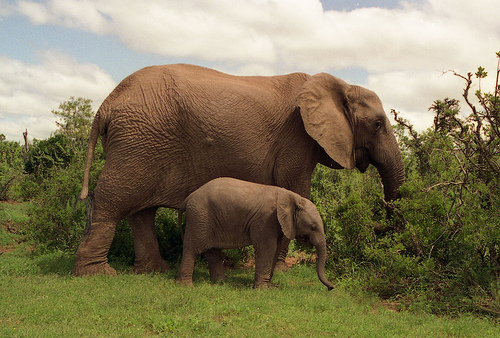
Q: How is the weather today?
A: It is cloudy.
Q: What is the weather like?
A: It is cloudy.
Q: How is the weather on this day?
A: It is cloudy.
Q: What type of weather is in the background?
A: It is cloudy.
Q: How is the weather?
A: It is cloudy.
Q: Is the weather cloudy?
A: Yes, it is cloudy.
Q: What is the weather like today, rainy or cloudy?
A: It is cloudy.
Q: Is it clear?
A: No, it is cloudy.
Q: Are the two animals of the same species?
A: Yes, all the animals are elephants.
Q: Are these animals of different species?
A: No, all the animals are elephants.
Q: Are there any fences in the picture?
A: No, there are no fences.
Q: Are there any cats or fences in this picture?
A: No, there are no fences or cats.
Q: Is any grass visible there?
A: Yes, there is grass.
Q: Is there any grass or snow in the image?
A: Yes, there is grass.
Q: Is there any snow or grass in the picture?
A: Yes, there is grass.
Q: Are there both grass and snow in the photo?
A: No, there is grass but no snow.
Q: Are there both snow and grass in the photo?
A: No, there is grass but no snow.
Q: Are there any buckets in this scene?
A: No, there are no buckets.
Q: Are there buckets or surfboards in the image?
A: No, there are no buckets or surfboards.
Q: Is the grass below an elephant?
A: Yes, the grass is below an elephant.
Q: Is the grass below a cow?
A: No, the grass is below an elephant.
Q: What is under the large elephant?
A: The grass is under the elephant.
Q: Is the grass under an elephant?
A: Yes, the grass is under an elephant.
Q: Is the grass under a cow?
A: No, the grass is under an elephant.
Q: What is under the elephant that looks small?
A: The grass is under the elephant.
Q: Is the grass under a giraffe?
A: No, the grass is under an elephant.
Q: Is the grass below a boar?
A: No, the grass is below the elephant.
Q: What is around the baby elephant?
A: The grass is around the elephant.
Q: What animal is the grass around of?
A: The grass is around the elephant.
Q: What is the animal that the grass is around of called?
A: The animal is an elephant.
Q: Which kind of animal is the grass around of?
A: The grass is around the elephant.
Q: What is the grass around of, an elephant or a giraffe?
A: The grass is around an elephant.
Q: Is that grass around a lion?
A: No, the grass is around the elephant.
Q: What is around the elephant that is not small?
A: The grass is around the elephant.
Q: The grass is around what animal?
A: The grass is around the elephant.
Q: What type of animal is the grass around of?
A: The grass is around the elephant.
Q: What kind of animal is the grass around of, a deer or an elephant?
A: The grass is around an elephant.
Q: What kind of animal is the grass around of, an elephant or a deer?
A: The grass is around an elephant.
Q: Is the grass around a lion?
A: No, the grass is around an elephant.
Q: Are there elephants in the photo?
A: Yes, there is an elephant.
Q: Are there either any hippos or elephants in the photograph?
A: Yes, there is an elephant.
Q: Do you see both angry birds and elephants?
A: No, there is an elephant but no angry birds.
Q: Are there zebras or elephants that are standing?
A: Yes, the elephant is standing.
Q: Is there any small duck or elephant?
A: Yes, there is a small elephant.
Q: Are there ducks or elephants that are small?
A: Yes, the elephant is small.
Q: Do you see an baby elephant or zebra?
A: Yes, there is a baby elephant.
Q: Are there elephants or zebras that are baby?
A: Yes, the elephant is a baby.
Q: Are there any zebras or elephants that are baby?
A: Yes, the elephant is a baby.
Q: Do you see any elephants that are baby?
A: Yes, there is a baby elephant.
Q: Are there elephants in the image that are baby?
A: Yes, there is an elephant that is a baby.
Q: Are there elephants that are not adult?
A: Yes, there is an baby elephant.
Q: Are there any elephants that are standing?
A: Yes, there is an elephant that is standing.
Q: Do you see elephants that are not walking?
A: Yes, there is an elephant that is standing .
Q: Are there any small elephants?
A: Yes, there is a small elephant.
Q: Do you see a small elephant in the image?
A: Yes, there is a small elephant.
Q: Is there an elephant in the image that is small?
A: Yes, there is an elephant that is small.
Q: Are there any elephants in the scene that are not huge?
A: Yes, there is a small elephant.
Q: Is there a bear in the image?
A: No, there are no bears.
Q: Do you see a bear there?
A: No, there are no bears.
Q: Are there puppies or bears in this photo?
A: No, there are no bears or puppies.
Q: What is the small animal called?
A: The animal is an elephant.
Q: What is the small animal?
A: The animal is an elephant.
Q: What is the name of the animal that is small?
A: The animal is an elephant.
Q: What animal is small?
A: The animal is an elephant.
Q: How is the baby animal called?
A: The animal is an elephant.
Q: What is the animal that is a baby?
A: The animal is an elephant.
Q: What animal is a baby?
A: The animal is an elephant.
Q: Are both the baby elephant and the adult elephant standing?
A: Yes, both the elephant and the elephant are standing.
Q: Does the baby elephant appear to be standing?
A: Yes, the elephant is standing.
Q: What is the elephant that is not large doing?
A: The elephant is standing.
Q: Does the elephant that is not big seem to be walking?
A: No, the elephant is standing.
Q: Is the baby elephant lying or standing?
A: The elephant is standing.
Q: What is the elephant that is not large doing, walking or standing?
A: The elephant is standing.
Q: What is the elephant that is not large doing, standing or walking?
A: The elephant is standing.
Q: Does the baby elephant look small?
A: Yes, the elephant is small.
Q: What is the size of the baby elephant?
A: The elephant is small.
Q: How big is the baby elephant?
A: The elephant is small.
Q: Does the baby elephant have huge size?
A: No, the elephant is small.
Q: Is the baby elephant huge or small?
A: The elephant is small.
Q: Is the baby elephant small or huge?
A: The elephant is small.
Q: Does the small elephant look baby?
A: Yes, the elephant is a baby.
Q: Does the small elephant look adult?
A: No, the elephant is a baby.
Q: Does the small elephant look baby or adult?
A: The elephant is a baby.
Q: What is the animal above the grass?
A: The animal is an elephant.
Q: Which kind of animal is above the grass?
A: The animal is an elephant.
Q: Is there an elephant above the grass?
A: Yes, there is an elephant above the grass.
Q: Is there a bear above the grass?
A: No, there is an elephant above the grass.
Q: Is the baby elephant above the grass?
A: Yes, the elephant is above the grass.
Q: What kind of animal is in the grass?
A: The animal is an elephant.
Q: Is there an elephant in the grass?
A: Yes, there is an elephant in the grass.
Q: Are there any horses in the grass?
A: No, there is an elephant in the grass.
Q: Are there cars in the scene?
A: No, there are no cars.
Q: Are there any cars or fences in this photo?
A: No, there are no cars or fences.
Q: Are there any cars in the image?
A: No, there are no cars.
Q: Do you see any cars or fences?
A: No, there are no cars or fences.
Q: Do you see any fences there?
A: No, there are no fences.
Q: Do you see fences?
A: No, there are no fences.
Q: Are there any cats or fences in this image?
A: No, there are no fences or cats.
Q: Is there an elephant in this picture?
A: Yes, there is an elephant.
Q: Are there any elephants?
A: Yes, there is an elephant.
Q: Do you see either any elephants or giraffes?
A: Yes, there is an elephant.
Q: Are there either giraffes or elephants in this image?
A: Yes, there is an elephant.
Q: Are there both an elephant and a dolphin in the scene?
A: No, there is an elephant but no dolphins.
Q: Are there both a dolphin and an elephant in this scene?
A: No, there is an elephant but no dolphins.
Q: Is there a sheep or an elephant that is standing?
A: Yes, the elephant is standing.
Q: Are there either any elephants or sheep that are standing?
A: Yes, the elephant is standing.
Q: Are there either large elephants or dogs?
A: Yes, there is a large elephant.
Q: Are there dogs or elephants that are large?
A: Yes, the elephant is large.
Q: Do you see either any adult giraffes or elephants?
A: Yes, there is an adult elephant.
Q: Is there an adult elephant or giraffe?
A: Yes, there is an adult elephant.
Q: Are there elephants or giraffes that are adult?
A: Yes, the elephant is adult.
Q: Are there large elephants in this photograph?
A: Yes, there is a large elephant.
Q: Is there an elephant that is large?
A: Yes, there is an elephant that is large.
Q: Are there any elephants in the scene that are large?
A: Yes, there is an elephant that is large.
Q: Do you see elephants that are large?
A: Yes, there is an elephant that is large.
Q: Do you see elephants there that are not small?
A: Yes, there is a large elephant.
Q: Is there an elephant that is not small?
A: Yes, there is a large elephant.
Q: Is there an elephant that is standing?
A: Yes, there is an elephant that is standing.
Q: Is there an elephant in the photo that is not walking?
A: Yes, there is an elephant that is standing.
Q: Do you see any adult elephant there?
A: Yes, there is an adult elephant.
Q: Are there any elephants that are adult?
A: Yes, there is an elephant that is adult.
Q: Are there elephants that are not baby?
A: Yes, there is a adult elephant.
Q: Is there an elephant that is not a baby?
A: Yes, there is a adult elephant.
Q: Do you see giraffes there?
A: No, there are no giraffes.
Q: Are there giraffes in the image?
A: No, there are no giraffes.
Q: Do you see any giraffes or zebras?
A: No, there are no giraffes or zebras.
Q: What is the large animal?
A: The animal is an elephant.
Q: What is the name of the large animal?
A: The animal is an elephant.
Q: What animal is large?
A: The animal is an elephant.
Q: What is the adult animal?
A: The animal is an elephant.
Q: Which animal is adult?
A: The animal is an elephant.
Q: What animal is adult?
A: The animal is an elephant.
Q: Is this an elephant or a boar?
A: This is an elephant.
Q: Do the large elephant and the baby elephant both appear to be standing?
A: Yes, both the elephant and the elephant are standing.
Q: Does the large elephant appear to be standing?
A: Yes, the elephant is standing.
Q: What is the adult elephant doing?
A: The elephant is standing.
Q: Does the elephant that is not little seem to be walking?
A: No, the elephant is standing.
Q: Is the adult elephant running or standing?
A: The elephant is standing.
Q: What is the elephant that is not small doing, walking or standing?
A: The elephant is standing.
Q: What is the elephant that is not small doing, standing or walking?
A: The elephant is standing.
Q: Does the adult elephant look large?
A: Yes, the elephant is large.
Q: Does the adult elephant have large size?
A: Yes, the elephant is large.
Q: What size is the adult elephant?
A: The elephant is large.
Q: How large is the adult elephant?
A: The elephant is large.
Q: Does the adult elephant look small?
A: No, the elephant is large.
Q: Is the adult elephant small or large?
A: The elephant is large.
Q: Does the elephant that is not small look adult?
A: Yes, the elephant is adult.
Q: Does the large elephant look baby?
A: No, the elephant is adult.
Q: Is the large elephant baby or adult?
A: The elephant is adult.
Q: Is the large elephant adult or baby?
A: The elephant is adult.